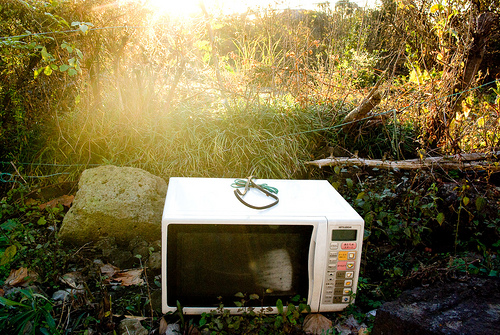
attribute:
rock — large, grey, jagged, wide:
[60, 166, 165, 242]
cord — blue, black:
[232, 174, 281, 211]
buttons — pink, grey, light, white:
[328, 241, 356, 307]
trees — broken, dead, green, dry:
[2, 1, 499, 334]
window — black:
[164, 220, 317, 313]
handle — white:
[311, 220, 331, 314]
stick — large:
[300, 147, 497, 177]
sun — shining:
[110, 0, 379, 33]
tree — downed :
[292, 148, 495, 177]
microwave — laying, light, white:
[157, 171, 362, 312]